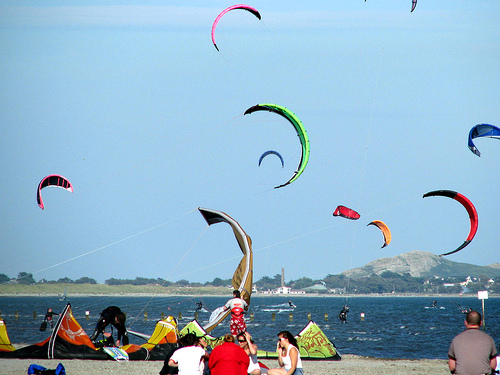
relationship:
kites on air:
[30, 4, 498, 257] [3, 4, 495, 281]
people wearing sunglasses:
[263, 330, 305, 375] [276, 335, 284, 343]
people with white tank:
[263, 330, 305, 375] [277, 344, 305, 369]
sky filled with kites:
[2, 4, 495, 243] [30, 4, 498, 257]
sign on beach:
[476, 287, 491, 303] [11, 276, 495, 374]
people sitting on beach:
[90, 311, 497, 375] [11, 276, 495, 374]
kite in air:
[419, 184, 482, 258] [3, 4, 495, 281]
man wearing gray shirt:
[441, 306, 499, 374] [443, 324, 499, 375]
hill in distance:
[300, 247, 499, 298] [4, 254, 499, 295]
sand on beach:
[310, 359, 441, 374] [11, 276, 495, 374]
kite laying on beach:
[303, 319, 344, 364] [11, 276, 495, 374]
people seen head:
[263, 330, 305, 375] [276, 329, 293, 353]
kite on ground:
[303, 319, 344, 364] [303, 356, 384, 375]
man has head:
[441, 306, 499, 374] [457, 307, 488, 336]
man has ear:
[441, 306, 499, 374] [460, 316, 468, 328]